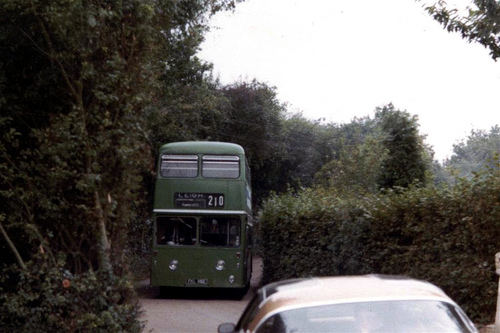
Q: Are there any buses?
A: Yes, there is a bus.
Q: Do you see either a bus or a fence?
A: Yes, there is a bus.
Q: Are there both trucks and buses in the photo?
A: No, there is a bus but no trucks.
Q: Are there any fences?
A: No, there are no fences.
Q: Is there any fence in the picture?
A: No, there are no fences.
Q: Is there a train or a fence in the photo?
A: No, there are no fences or trains.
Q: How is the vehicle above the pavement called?
A: The vehicle is a bus.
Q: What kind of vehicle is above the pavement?
A: The vehicle is a bus.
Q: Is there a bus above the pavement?
A: Yes, there is a bus above the pavement.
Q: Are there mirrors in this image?
A: Yes, there is a mirror.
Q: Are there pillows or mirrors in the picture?
A: Yes, there is a mirror.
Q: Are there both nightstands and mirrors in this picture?
A: No, there is a mirror but no nightstands.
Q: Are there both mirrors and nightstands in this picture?
A: No, there is a mirror but no nightstands.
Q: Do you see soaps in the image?
A: No, there are no soaps.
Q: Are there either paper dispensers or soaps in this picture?
A: No, there are no soaps or paper dispensers.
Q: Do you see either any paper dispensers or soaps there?
A: No, there are no soaps or paper dispensers.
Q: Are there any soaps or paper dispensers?
A: No, there are no soaps or paper dispensers.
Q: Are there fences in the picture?
A: No, there are no fences.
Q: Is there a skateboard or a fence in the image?
A: No, there are no fences or skateboards.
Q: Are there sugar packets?
A: No, there are no sugar packets.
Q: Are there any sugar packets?
A: No, there are no sugar packets.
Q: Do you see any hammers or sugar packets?
A: No, there are no sugar packets or hammers.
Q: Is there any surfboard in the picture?
A: No, there are no surfboards.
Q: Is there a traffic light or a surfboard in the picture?
A: No, there are no surfboards or traffic lights.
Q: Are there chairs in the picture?
A: No, there are no chairs.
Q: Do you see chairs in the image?
A: No, there are no chairs.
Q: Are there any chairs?
A: No, there are no chairs.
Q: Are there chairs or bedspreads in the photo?
A: No, there are no chairs or bedspreads.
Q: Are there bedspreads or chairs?
A: No, there are no chairs or bedspreads.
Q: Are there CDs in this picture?
A: No, there are no cds.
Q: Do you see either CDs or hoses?
A: No, there are no CDs or hoses.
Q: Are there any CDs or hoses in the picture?
A: No, there are no CDs or hoses.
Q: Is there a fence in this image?
A: No, there are no fences.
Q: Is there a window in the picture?
A: Yes, there is a window.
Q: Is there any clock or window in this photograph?
A: Yes, there is a window.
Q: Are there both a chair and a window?
A: No, there is a window but no chairs.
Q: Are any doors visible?
A: No, there are no doors.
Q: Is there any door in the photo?
A: No, there are no doors.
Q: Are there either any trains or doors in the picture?
A: No, there are no doors or trains.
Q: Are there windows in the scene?
A: Yes, there is a window.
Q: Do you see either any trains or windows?
A: Yes, there is a window.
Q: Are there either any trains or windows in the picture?
A: Yes, there is a window.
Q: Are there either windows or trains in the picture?
A: Yes, there is a window.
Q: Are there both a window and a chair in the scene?
A: No, there is a window but no chairs.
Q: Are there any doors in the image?
A: No, there are no doors.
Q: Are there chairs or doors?
A: No, there are no doors or chairs.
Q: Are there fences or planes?
A: No, there are no fences or planes.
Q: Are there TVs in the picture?
A: No, there are no tvs.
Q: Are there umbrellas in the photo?
A: No, there are no umbrellas.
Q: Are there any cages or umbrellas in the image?
A: No, there are no umbrellas or cages.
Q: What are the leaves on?
A: The leaves are on the trees.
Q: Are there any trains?
A: No, there are no trains.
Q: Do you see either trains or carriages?
A: No, there are no trains or carriages.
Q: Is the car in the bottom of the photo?
A: Yes, the car is in the bottom of the image.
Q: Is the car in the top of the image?
A: No, the car is in the bottom of the image.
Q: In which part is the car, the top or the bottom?
A: The car is in the bottom of the image.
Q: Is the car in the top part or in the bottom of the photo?
A: The car is in the bottom of the image.